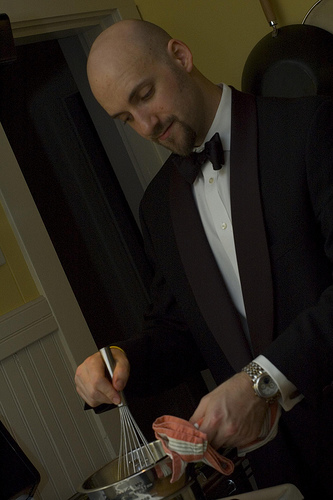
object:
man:
[86, 17, 330, 499]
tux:
[82, 84, 333, 498]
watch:
[242, 361, 282, 407]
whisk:
[99, 343, 158, 479]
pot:
[82, 437, 187, 499]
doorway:
[1, 0, 250, 499]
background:
[0, 0, 333, 322]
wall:
[136, 0, 333, 95]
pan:
[240, 1, 333, 103]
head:
[86, 18, 221, 156]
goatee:
[149, 115, 196, 159]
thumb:
[112, 349, 129, 392]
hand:
[74, 345, 132, 408]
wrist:
[241, 349, 301, 422]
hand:
[187, 361, 280, 453]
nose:
[129, 102, 157, 137]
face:
[88, 71, 202, 156]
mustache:
[141, 113, 177, 141]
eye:
[139, 84, 153, 104]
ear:
[168, 38, 192, 76]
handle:
[258, 0, 280, 29]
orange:
[152, 415, 203, 437]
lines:
[0, 127, 129, 500]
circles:
[256, 373, 276, 401]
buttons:
[221, 220, 228, 231]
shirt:
[183, 83, 254, 359]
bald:
[86, 19, 178, 97]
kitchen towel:
[151, 415, 233, 483]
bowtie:
[174, 135, 225, 185]